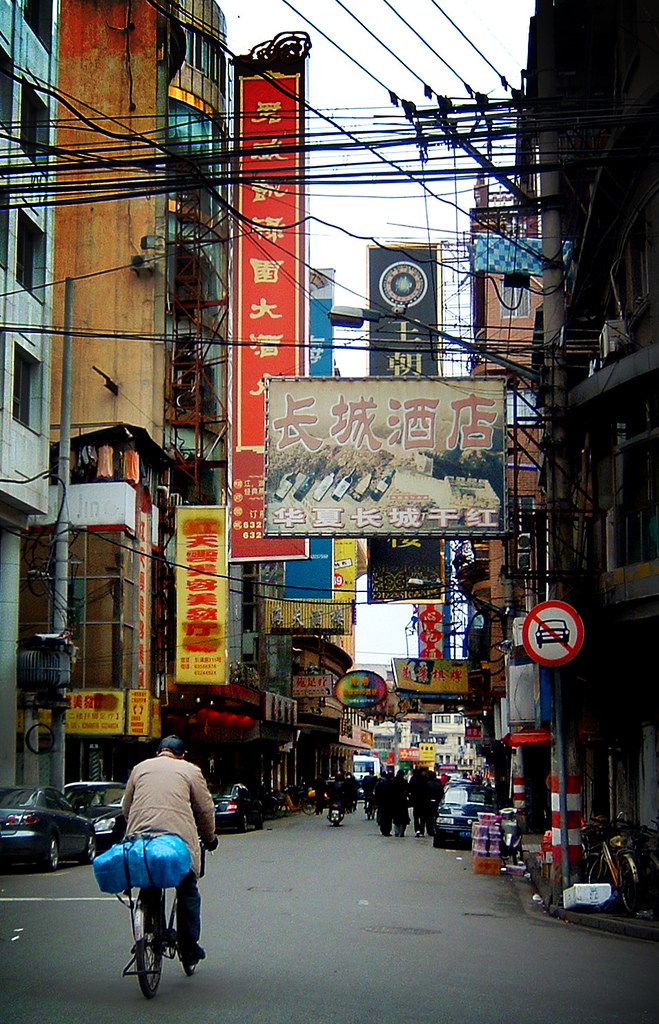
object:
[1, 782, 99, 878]
car